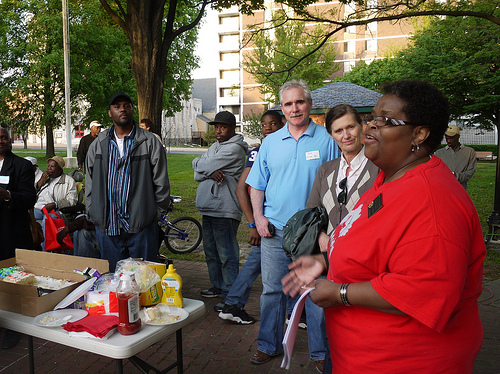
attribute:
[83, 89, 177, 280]
man — standing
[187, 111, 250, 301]
man — standing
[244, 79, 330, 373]
man — standing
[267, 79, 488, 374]
woman — standing, talking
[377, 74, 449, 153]
hair — short, black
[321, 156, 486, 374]
shirt — red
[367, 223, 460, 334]
sleeve — short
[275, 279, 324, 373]
paper — white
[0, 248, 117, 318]
box — cardboard